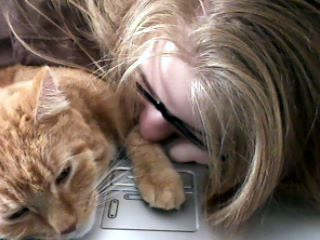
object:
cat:
[0, 64, 186, 240]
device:
[96, 168, 202, 232]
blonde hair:
[3, 0, 320, 229]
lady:
[4, 0, 320, 227]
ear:
[33, 63, 66, 118]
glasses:
[128, 64, 209, 152]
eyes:
[54, 161, 74, 187]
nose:
[45, 204, 78, 236]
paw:
[147, 190, 158, 208]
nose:
[139, 110, 172, 140]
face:
[0, 134, 98, 240]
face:
[135, 56, 200, 144]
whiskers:
[85, 140, 139, 206]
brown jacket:
[0, 0, 100, 66]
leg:
[125, 129, 183, 208]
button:
[107, 199, 119, 217]